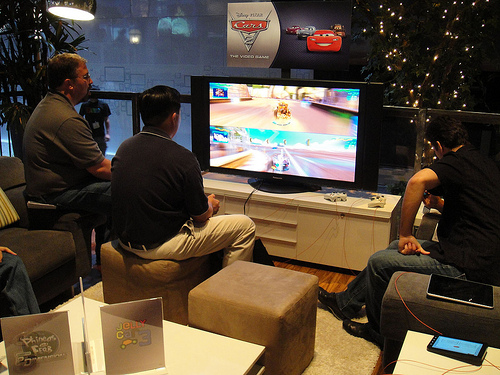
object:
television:
[182, 70, 381, 197]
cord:
[243, 178, 264, 218]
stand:
[182, 161, 410, 273]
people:
[14, 35, 500, 341]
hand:
[394, 231, 429, 257]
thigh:
[326, 232, 465, 320]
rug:
[85, 238, 374, 372]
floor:
[4, 226, 383, 360]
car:
[284, 15, 348, 55]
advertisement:
[224, 0, 360, 68]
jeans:
[0, 244, 46, 324]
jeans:
[332, 238, 466, 318]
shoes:
[340, 311, 379, 344]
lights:
[378, 0, 493, 155]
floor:
[198, 237, 417, 286]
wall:
[8, 4, 218, 78]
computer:
[427, 329, 486, 360]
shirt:
[107, 131, 216, 247]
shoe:
[311, 281, 353, 322]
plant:
[357, 0, 496, 160]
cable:
[382, 267, 437, 334]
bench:
[97, 245, 227, 332]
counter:
[393, 328, 498, 375]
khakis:
[118, 210, 257, 267]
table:
[233, 176, 447, 221]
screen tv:
[184, 66, 383, 182]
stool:
[185, 257, 321, 375]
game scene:
[206, 76, 366, 173]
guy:
[26, 44, 137, 270]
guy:
[108, 84, 258, 274]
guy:
[312, 103, 500, 344]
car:
[303, 28, 348, 53]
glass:
[72, 73, 93, 83]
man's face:
[65, 60, 94, 101]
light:
[40, 2, 99, 24]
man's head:
[45, 51, 91, 105]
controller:
[322, 189, 349, 202]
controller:
[366, 191, 389, 211]